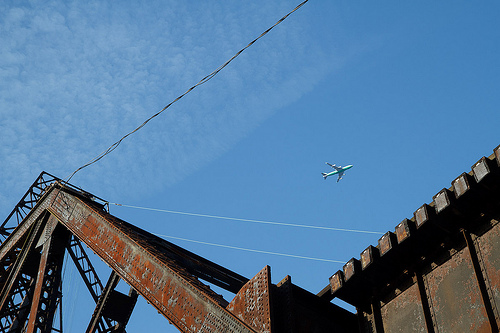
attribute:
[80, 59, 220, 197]
cable — metal, large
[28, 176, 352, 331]
metal — rusty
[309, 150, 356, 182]
plane — large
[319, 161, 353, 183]
airplane — flying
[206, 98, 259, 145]
clouds — white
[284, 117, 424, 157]
sky — blue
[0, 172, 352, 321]
beam — steel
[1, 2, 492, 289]
sky — blue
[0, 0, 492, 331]
sky — blue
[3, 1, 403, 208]
clouds — white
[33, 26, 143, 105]
clouds — white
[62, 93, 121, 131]
clouds — white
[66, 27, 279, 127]
clouds — white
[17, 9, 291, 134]
clouds — white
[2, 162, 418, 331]
contraption — metal